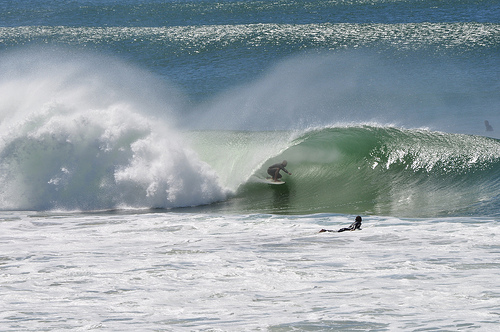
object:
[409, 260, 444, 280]
ripples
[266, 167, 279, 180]
leg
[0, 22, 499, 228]
waves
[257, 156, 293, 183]
person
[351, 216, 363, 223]
head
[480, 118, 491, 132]
person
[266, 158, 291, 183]
man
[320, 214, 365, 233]
person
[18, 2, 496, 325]
water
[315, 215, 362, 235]
person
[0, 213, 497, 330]
surf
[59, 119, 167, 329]
white foam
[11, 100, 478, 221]
wave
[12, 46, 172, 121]
mist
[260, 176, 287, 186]
surfboard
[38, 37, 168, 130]
spray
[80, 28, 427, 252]
ocean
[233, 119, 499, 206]
wave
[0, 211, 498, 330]
foam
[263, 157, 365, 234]
two surfers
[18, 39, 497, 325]
ocean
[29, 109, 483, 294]
beach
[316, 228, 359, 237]
surfboard